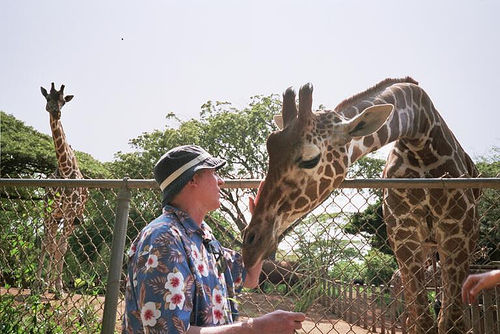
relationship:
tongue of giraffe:
[241, 255, 263, 290] [233, 71, 475, 332]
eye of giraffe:
[297, 151, 324, 169] [233, 71, 475, 332]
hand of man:
[240, 307, 304, 332] [256, 306, 306, 332]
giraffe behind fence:
[25, 75, 90, 303] [5, 173, 499, 328]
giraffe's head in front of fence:
[238, 82, 390, 285] [5, 173, 499, 328]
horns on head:
[276, 81, 356, 125] [231, 127, 363, 245]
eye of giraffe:
[291, 144, 324, 173] [239, 75, 484, 333]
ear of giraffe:
[345, 104, 392, 145] [239, 75, 484, 333]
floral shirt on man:
[123, 202, 237, 331] [122, 145, 306, 332]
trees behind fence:
[145, 110, 365, 161] [28, 174, 440, 325]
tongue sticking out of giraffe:
[242, 257, 263, 289] [239, 75, 484, 333]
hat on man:
[152, 143, 227, 209] [80, 121, 300, 331]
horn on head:
[280, 86, 299, 129] [247, 73, 359, 285]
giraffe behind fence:
[32, 81, 90, 303] [5, 173, 499, 328]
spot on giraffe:
[428, 118, 463, 163] [233, 71, 475, 332]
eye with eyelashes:
[297, 151, 324, 169] [300, 153, 323, 168]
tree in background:
[103, 86, 379, 284] [2, 7, 489, 282]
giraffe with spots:
[239, 75, 484, 333] [398, 194, 416, 253]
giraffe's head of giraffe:
[239, 82, 394, 269] [239, 75, 484, 333]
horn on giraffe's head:
[300, 83, 313, 124] [239, 82, 394, 269]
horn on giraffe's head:
[274, 80, 305, 133] [239, 82, 394, 269]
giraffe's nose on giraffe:
[235, 225, 265, 272] [233, 71, 475, 332]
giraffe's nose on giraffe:
[44, 102, 61, 122] [233, 71, 475, 332]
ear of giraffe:
[62, 91, 75, 104] [219, 85, 478, 312]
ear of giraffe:
[35, 80, 47, 99] [219, 85, 478, 312]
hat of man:
[136, 133, 223, 186] [104, 146, 274, 332]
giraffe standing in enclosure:
[239, 75, 484, 333] [4, 129, 484, 328]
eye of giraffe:
[297, 151, 324, 169] [263, 90, 467, 331]